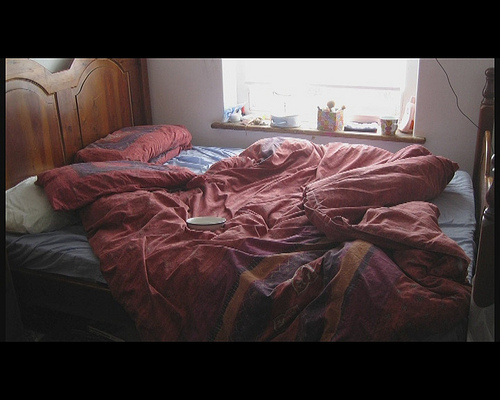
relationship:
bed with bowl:
[11, 51, 492, 338] [183, 213, 231, 232]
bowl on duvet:
[183, 213, 231, 232] [74, 138, 463, 341]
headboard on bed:
[0, 57, 157, 189] [11, 51, 492, 338]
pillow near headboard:
[5, 170, 78, 240] [0, 57, 157, 189]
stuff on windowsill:
[226, 97, 421, 138] [203, 97, 427, 144]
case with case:
[69, 118, 198, 170] [77, 118, 194, 164]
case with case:
[24, 142, 202, 213] [34, 153, 202, 214]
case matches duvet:
[77, 118, 194, 164] [74, 138, 463, 341]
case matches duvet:
[34, 153, 202, 214] [74, 138, 463, 341]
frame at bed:
[463, 66, 500, 308] [11, 51, 492, 338]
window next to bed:
[214, 58, 423, 155] [11, 51, 492, 338]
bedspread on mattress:
[33, 121, 473, 341] [11, 130, 477, 333]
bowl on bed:
[183, 213, 231, 232] [11, 51, 492, 338]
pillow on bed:
[5, 170, 78, 240] [11, 51, 492, 338]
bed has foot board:
[11, 51, 492, 338] [463, 66, 500, 308]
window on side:
[214, 58, 423, 155] [146, 62, 497, 153]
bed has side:
[11, 51, 492, 338] [146, 62, 497, 153]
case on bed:
[69, 118, 198, 170] [11, 51, 492, 338]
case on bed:
[24, 142, 202, 213] [11, 51, 492, 338]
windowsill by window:
[203, 97, 427, 144] [214, 58, 423, 155]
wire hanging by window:
[432, 60, 485, 138] [214, 58, 423, 155]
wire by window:
[432, 60, 485, 138] [214, 58, 423, 155]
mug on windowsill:
[380, 117, 399, 133] [203, 97, 427, 144]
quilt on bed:
[74, 138, 463, 341] [11, 51, 492, 338]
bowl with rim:
[183, 213, 231, 232] [186, 221, 227, 228]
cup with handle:
[380, 117, 399, 133] [391, 124, 399, 130]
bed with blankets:
[11, 51, 492, 338] [74, 138, 463, 341]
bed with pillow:
[11, 51, 492, 338] [5, 170, 78, 240]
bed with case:
[11, 51, 492, 338] [69, 118, 198, 170]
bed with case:
[11, 51, 492, 338] [24, 142, 202, 213]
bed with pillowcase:
[11, 51, 492, 338] [77, 118, 194, 164]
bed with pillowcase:
[11, 51, 492, 338] [34, 153, 202, 214]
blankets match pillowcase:
[74, 138, 463, 341] [34, 153, 202, 214]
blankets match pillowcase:
[80, 127, 479, 345] [77, 118, 194, 164]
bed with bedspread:
[11, 51, 492, 338] [33, 121, 473, 341]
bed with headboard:
[11, 51, 492, 338] [0, 57, 157, 189]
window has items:
[214, 58, 423, 155] [226, 97, 421, 138]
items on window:
[226, 97, 421, 138] [214, 58, 423, 155]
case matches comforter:
[69, 118, 198, 170] [74, 138, 463, 341]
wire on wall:
[432, 60, 485, 138] [144, 57, 499, 177]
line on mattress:
[12, 264, 111, 291] [11, 130, 477, 333]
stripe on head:
[123, 69, 137, 128] [0, 57, 157, 189]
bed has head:
[11, 51, 492, 338] [0, 57, 157, 189]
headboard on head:
[0, 57, 157, 189] [0, 57, 157, 189]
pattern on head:
[8, 59, 140, 180] [0, 57, 157, 189]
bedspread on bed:
[33, 121, 473, 341] [11, 51, 492, 338]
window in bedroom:
[214, 58, 423, 155] [2, 54, 500, 336]